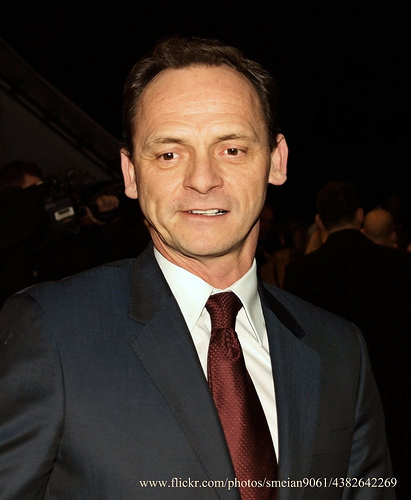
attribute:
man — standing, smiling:
[2, 36, 397, 500]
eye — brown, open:
[154, 147, 182, 162]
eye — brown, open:
[220, 146, 250, 159]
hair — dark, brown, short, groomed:
[119, 34, 279, 151]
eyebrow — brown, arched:
[214, 129, 255, 148]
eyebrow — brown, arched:
[136, 135, 185, 153]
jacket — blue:
[0, 242, 397, 497]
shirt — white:
[147, 247, 289, 470]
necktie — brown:
[203, 293, 284, 500]